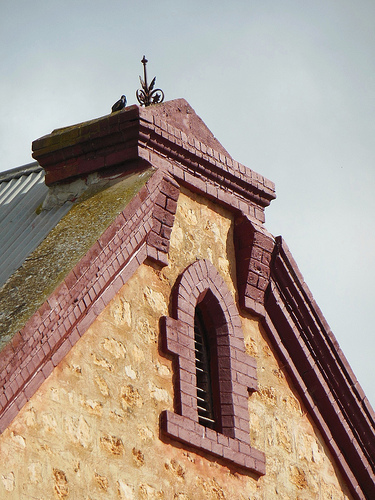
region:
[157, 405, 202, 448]
red brick window framing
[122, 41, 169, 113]
decorative lightning rod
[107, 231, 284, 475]
arched window on building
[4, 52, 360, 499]
peak of a unique building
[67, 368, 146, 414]
brown stone looking material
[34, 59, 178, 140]
a bird resting on a roof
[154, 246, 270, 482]
a architctural arch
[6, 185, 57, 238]
metal roofing material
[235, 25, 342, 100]
a clear, greyish sky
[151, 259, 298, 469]
a window with shadow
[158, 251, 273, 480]
arched red brick around window opening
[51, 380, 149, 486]
beige mottled concrete wall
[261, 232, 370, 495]
red brick on roof eave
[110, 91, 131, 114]
black bird sitting on roof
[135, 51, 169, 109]
scrolled iron decoration on roof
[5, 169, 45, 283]
aluminum slates on roof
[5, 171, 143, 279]
moss growing on concrete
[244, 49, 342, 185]
pale blue sky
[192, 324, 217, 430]
white louvres on window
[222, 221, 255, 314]
shadow cast by brick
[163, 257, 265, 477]
a window in the wall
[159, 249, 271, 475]
the window frame is brick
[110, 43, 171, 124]
a decorative trim on top of the building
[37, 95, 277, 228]
the rooftop is red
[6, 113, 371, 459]
the trim is red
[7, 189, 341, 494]
the front is beige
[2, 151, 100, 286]
the siding is metal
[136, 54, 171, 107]
the decoration is metal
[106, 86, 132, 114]
a bird on the building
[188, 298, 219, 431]
a grid in the window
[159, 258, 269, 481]
Large brick framed window.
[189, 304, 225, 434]
Dark window inside the bricks.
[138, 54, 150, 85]
Pointy rod on top of the roof.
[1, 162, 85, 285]
Metal roof that is gray in color.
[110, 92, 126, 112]
Bird on top of a building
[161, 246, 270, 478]
Large red arched brick area around a window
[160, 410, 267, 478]
Bottom brick window sill.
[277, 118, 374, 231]
Gray sky to the right of the building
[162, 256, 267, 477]
Large bricked arched window frame.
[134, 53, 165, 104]
Pointy and round decoration at the top of the building.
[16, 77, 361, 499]
The top of a building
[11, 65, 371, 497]
The peak of a building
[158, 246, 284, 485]
A window on a building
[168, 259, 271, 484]
Bricks around a window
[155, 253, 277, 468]
Bricks around a window on a building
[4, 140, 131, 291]
The roof of a building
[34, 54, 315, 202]
Bricks on the top of a building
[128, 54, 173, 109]
Decorative iron on top of a building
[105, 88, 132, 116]
A bird on the top of a building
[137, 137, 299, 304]
Brick on the front of a building